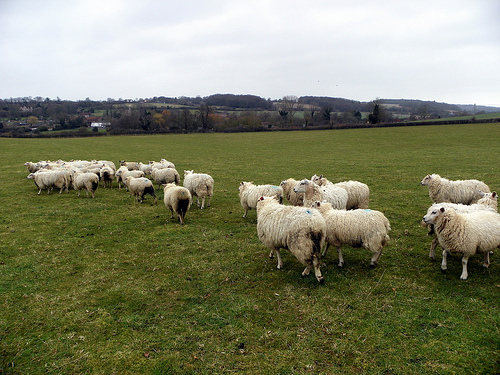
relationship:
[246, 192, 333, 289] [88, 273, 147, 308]
sheep in grass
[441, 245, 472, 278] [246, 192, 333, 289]
leg of sheep